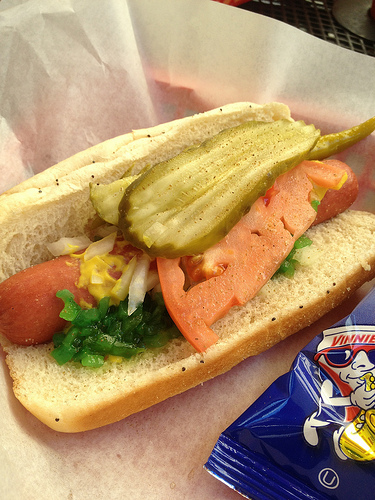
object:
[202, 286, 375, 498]
bag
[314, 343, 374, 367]
sunglasses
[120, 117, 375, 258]
pickle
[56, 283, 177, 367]
relish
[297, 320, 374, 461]
character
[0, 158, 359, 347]
dog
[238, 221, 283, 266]
pepper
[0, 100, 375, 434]
bread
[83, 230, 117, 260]
onion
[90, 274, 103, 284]
onion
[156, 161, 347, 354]
tomato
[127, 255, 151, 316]
onion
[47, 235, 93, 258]
onion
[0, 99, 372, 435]
bun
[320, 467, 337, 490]
letter u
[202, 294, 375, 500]
potato chips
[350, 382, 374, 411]
right hand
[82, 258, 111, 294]
mustard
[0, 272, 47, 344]
end